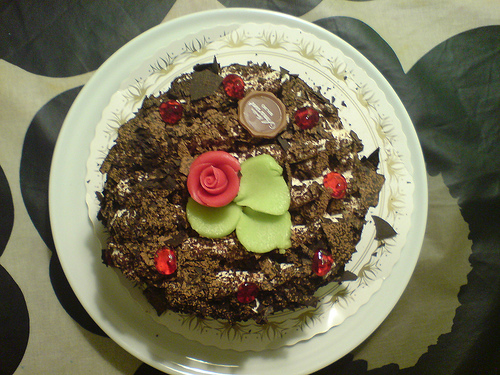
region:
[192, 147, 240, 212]
The rose on the cake.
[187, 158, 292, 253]
The green leaves decorations on the cake.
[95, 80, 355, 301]
The small red flowers on the cake.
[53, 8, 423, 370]
The white plate the cake is on.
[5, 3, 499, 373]
The table cloth under the plate.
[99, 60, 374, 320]
The chocolate icing and crumbs on the cake.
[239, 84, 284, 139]
The brown circle with white writing on the cake.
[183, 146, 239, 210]
red rose made of icing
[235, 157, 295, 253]
green icing for leaves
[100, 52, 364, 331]
a decorated chocolate cake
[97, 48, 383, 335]
decorated cake on a plate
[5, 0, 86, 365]
black and white table cloth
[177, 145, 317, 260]
icing made to look like a rose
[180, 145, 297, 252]
flower and leaves made of icing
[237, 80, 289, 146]
choclate shaped like a coin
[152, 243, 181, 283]
red jelly drop on a cake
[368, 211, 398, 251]
chocolate piece on plate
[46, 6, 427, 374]
white round ceramic plate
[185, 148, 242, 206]
pink fondant rose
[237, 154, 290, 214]
green fondant leaf next to rose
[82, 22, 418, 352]
white doily on top of the plate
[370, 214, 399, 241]
chocolate shaving on top of the doily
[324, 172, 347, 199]
candied cherry on top of the cake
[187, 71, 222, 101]
chocolate shaving on top of the cake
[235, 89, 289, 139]
brown disc on top of the cake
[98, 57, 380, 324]
cake on top of the doily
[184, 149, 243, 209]
rose on top of the cake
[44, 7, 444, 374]
a white plate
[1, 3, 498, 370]
a dessert plate on a table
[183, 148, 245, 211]
a candy flower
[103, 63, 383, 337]
a yummy dessert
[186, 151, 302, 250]
a candy rose and petels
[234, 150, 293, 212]
a yellow candy petal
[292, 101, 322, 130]
a chocolate chip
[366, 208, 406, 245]
a chocolate flake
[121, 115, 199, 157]
a brownie mixed into dessert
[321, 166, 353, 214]
red flower on cake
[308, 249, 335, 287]
red flower on cake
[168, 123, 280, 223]
The cake has a red flower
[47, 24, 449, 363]
The cake has chocolate frosting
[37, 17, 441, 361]
The cake is on a white plate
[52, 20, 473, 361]
The white plate is round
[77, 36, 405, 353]
The cake is round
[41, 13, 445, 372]
a large white plate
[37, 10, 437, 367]
a cake on a plate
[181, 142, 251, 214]
red rose on a cake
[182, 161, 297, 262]
green leaves on the cake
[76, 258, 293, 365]
shadow of the cake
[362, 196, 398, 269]
crumbs on the plate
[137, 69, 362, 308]
red candies on the cake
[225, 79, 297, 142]
brown emblem on cake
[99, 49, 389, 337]
the cake is brown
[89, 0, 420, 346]
white doily under the cake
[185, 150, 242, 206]
Red rose on top of a cake.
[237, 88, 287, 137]
Brown pendant with writing on top of a cake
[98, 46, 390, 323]
Cake on a white plate.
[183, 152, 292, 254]
Red rose with green leaves on a cake.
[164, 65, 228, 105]
Large chocolate shaving at the top of a cake.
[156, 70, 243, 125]
Two red candies at the top of the cake.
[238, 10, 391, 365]
Right side of a cake on a plate.